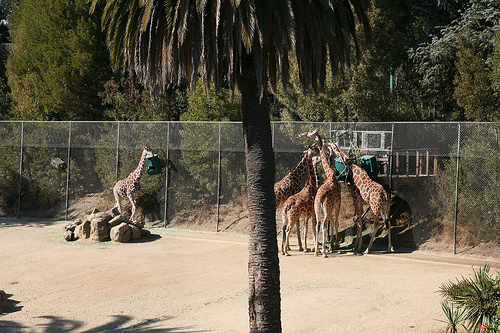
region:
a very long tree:
[202, 128, 298, 331]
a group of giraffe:
[281, 125, 408, 255]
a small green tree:
[421, 235, 498, 331]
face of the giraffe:
[133, 142, 178, 184]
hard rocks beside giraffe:
[71, 210, 151, 247]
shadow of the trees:
[46, 298, 156, 331]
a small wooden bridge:
[382, 139, 445, 179]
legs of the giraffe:
[277, 223, 413, 258]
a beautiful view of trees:
[9, 26, 496, 188]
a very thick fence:
[46, 117, 490, 259]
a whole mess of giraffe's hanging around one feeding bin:
[278, 118, 408, 270]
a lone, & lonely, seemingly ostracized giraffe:
[105, 136, 167, 236]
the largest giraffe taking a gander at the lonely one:
[286, 118, 344, 270]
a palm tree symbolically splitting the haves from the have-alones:
[85, 0, 426, 331]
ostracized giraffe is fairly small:
[99, 139, 159, 226]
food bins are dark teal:
[135, 153, 382, 183]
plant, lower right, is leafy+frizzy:
[430, 250, 499, 331]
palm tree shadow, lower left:
[0, 296, 225, 328]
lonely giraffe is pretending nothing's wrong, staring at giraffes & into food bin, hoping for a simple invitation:
[107, 138, 163, 230]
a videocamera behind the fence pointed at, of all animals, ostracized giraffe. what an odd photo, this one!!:
[45, 148, 70, 178]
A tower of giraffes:
[276, 126, 406, 278]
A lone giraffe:
[106, 136, 171, 221]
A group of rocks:
[58, 199, 158, 251]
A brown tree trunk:
[232, 106, 294, 327]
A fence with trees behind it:
[7, 107, 112, 210]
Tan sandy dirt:
[26, 250, 236, 321]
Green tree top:
[3, 5, 102, 115]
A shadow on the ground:
[2, 307, 200, 332]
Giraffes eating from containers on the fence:
[99, 42, 427, 329]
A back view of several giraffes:
[276, 126, 403, 265]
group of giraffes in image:
[5, 118, 402, 319]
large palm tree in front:
[167, 44, 301, 304]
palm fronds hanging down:
[2, 15, 346, 106]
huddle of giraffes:
[251, 127, 385, 277]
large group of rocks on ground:
[41, 201, 166, 265]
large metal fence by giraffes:
[21, 87, 472, 252]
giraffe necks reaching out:
[258, 134, 376, 181]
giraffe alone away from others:
[32, 115, 163, 267]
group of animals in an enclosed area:
[42, 75, 422, 313]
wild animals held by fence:
[68, 80, 412, 292]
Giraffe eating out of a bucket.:
[138, 142, 189, 209]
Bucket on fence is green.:
[138, 141, 178, 190]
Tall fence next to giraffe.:
[71, 107, 173, 262]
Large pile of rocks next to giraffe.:
[62, 203, 147, 258]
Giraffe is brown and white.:
[109, 149, 180, 239]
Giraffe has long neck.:
[121, 147, 167, 194]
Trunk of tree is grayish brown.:
[220, 157, 295, 317]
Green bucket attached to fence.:
[356, 146, 391, 206]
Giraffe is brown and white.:
[336, 158, 410, 249]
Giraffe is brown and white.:
[289, 155, 322, 218]